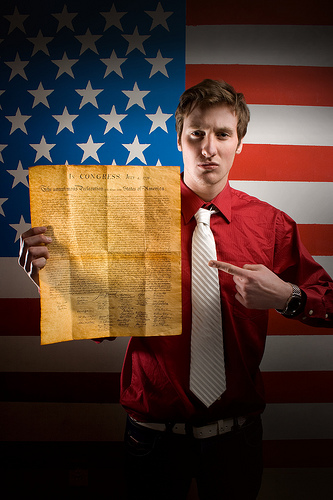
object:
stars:
[0, 0, 174, 243]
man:
[17, 78, 333, 499]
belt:
[127, 413, 259, 440]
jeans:
[120, 412, 263, 500]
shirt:
[90, 170, 333, 422]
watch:
[274, 280, 302, 319]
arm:
[274, 211, 332, 329]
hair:
[174, 78, 250, 152]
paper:
[28, 165, 182, 346]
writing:
[38, 172, 171, 330]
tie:
[189, 205, 226, 407]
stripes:
[0, 0, 332, 499]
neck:
[181, 168, 230, 209]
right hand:
[17, 225, 52, 290]